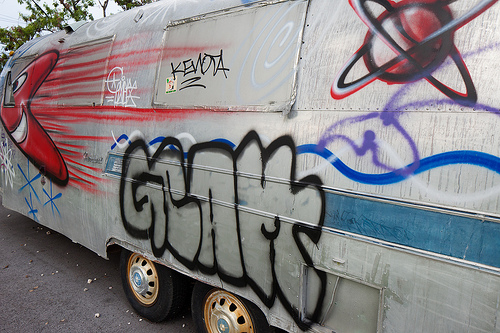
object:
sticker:
[165, 76, 178, 94]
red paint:
[24, 42, 212, 195]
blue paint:
[110, 133, 498, 187]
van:
[1, 1, 499, 331]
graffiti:
[115, 128, 327, 327]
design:
[0, 47, 66, 188]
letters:
[96, 64, 143, 109]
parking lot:
[4, 206, 244, 331]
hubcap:
[205, 291, 253, 332]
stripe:
[321, 188, 499, 270]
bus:
[0, 0, 497, 331]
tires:
[118, 248, 192, 324]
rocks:
[77, 264, 110, 318]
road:
[2, 211, 222, 331]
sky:
[2, 0, 119, 59]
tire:
[190, 281, 269, 333]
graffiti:
[168, 49, 230, 91]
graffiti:
[326, 0, 499, 108]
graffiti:
[1, 48, 74, 185]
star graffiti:
[15, 163, 64, 221]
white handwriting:
[104, 65, 140, 108]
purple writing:
[317, 85, 443, 172]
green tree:
[2, 1, 67, 32]